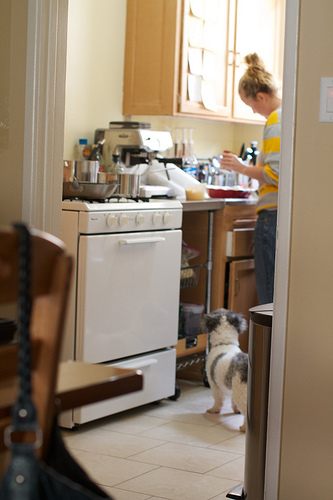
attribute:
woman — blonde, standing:
[220, 52, 281, 306]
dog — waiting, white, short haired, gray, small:
[202, 303, 249, 435]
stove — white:
[61, 198, 184, 428]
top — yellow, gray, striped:
[255, 108, 282, 215]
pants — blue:
[253, 210, 275, 307]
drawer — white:
[72, 346, 177, 428]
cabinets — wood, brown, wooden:
[122, 0, 284, 128]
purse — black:
[5, 220, 114, 499]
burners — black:
[64, 194, 152, 206]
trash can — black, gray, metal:
[226, 301, 278, 499]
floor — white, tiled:
[61, 374, 247, 499]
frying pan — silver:
[64, 176, 121, 200]